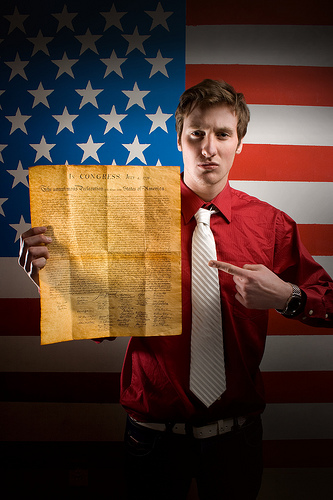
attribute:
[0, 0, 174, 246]
stars — white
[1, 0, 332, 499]
flag — red, blue, white, american flag, american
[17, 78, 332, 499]
man — standing, pointing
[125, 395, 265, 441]
belt — white, light-colored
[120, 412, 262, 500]
jeans — black, dark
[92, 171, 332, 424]
shirt — red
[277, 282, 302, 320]
watch — metallic, big, silver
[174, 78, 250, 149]
hair — brown, short, blonde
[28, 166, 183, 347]
paper — parchment, yellow, old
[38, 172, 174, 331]
writing — black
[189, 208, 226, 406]
tie — striped, wide, white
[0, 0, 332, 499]
stripes — red